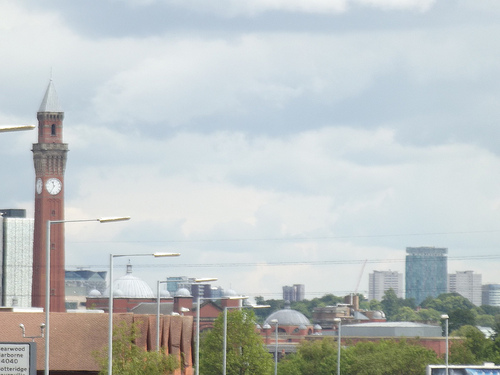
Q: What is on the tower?
A: A clock face.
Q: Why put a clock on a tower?
A: So people on the street can see the time.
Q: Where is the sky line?
A: Across the city.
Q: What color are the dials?
A: White.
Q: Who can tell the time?
A: Pedestrians.